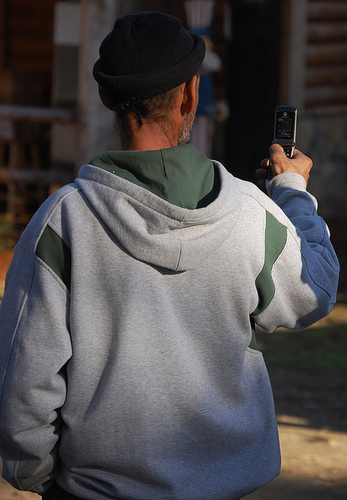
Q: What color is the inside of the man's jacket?
A: Green.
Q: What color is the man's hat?
A: Black.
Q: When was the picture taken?
A: Daytime.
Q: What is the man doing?
A: Using his phone.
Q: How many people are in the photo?
A: One.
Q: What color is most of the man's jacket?
A: Grey.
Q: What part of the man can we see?
A: The back.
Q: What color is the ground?
A: Tan.